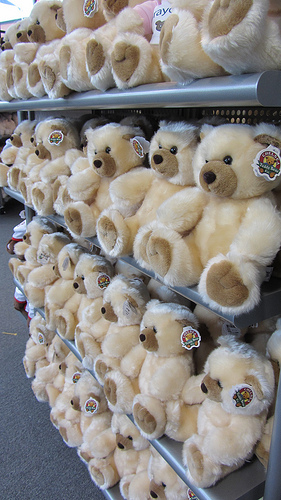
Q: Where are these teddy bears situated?
A: On shelves.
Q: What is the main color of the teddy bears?
A: Ivory.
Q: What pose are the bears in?
A: Sitting.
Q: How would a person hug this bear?
A: By squeezing.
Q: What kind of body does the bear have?
A: Plush.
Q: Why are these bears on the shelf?
A: For selling.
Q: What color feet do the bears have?
A: Brown.